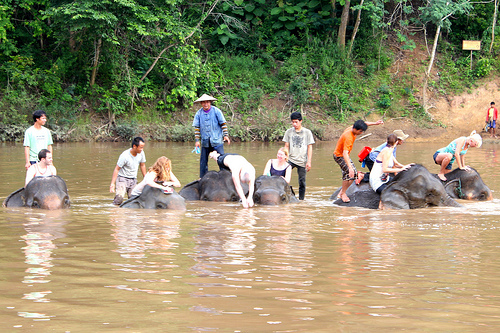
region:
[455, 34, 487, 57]
yellow sign on shore of river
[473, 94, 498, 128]
man standing on shore of river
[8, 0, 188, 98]
trees covered in green leaves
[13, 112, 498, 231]
group of people riding elephants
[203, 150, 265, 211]
man diving in to water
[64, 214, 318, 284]
reflection of people on water surface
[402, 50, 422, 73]
hillside covered in dirt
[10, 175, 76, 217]
elephant crossing river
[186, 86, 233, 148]
man in blue shirt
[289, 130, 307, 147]
design on front of shirt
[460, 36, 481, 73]
sign in the forest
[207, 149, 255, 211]
white guy diving over elephant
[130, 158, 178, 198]
red haired girl on elephant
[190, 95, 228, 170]
guy with blue shirt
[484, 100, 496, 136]
kid with red jacket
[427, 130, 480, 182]
blonde girl on elephant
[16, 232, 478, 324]
very muddy river water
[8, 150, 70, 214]
guy sitting on top of elephant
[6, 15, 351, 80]
green lush rain forest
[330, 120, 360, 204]
guy with orange shirt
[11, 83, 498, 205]
group of people playing with elephants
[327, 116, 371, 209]
man wearing orange shirt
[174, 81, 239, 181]
man wearing blue shirt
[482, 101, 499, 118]
person in red on the shoreline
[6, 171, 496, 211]
group of elephants in the water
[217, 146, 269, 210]
person diving into the water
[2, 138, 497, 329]
water the elephants and people are in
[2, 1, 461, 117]
trees along the shoreline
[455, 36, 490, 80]
sign posted on the shoreline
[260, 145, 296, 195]
women sitting in dark colored tanktop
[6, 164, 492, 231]
six elephants in the water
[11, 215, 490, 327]
the water is muddy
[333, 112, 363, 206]
a boy with an orange shirt standing on an elephant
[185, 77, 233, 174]
a person with a hat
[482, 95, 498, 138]
a boy standing on the bank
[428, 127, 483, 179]
a girl starting to stand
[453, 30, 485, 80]
a sign in the dirt by the trees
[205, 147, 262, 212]
a person diving into the water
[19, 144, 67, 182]
a man sitting on an elephant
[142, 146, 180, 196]
a lady with long red hair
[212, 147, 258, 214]
Man diving into brown water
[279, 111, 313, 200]
Man wearing gray shirt standing behind woman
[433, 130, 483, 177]
Woman climbing on top of elephant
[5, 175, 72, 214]
Elephant in brown water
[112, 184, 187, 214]
Elephant in brown water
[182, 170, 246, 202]
Elephant in brown water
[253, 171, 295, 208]
Elephant in brown water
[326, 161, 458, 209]
Elephant in brown water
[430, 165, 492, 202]
Elephant in brown water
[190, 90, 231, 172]
Man wearing Chinese straw hat